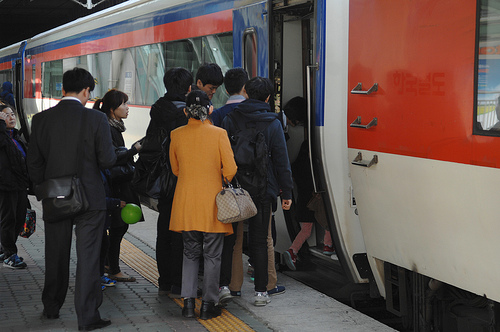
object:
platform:
[0, 201, 399, 332]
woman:
[168, 90, 236, 318]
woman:
[0, 101, 30, 272]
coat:
[168, 120, 238, 233]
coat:
[0, 126, 30, 195]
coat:
[107, 119, 145, 226]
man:
[25, 66, 119, 327]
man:
[156, 68, 193, 296]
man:
[196, 63, 224, 100]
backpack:
[224, 115, 278, 204]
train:
[0, 0, 499, 332]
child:
[92, 90, 141, 283]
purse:
[20, 208, 36, 237]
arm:
[219, 130, 236, 181]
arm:
[170, 129, 177, 176]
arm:
[268, 118, 292, 201]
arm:
[95, 113, 117, 168]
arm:
[26, 115, 46, 193]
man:
[212, 77, 294, 306]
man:
[225, 68, 249, 104]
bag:
[35, 175, 89, 223]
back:
[33, 109, 103, 212]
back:
[173, 126, 224, 199]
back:
[224, 111, 277, 188]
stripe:
[119, 235, 254, 330]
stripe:
[26, 0, 233, 55]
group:
[1, 64, 296, 332]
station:
[0, 0, 499, 332]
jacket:
[146, 96, 192, 199]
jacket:
[25, 99, 116, 211]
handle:
[351, 82, 378, 94]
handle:
[350, 116, 377, 129]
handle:
[351, 152, 378, 168]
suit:
[28, 100, 117, 327]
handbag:
[215, 174, 257, 223]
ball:
[120, 203, 142, 224]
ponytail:
[93, 99, 102, 109]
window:
[40, 32, 235, 105]